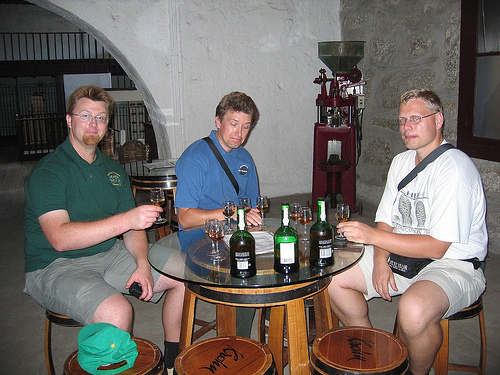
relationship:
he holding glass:
[21, 83, 189, 369] [142, 185, 167, 228]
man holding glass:
[175, 91, 262, 231] [253, 191, 272, 219]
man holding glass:
[321, 89, 489, 375] [335, 203, 349, 231]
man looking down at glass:
[169, 91, 306, 255] [208, 179, 256, 219]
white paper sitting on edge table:
[218, 225, 286, 267] [147, 217, 365, 289]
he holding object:
[21, 83, 189, 369] [124, 274, 152, 301]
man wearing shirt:
[306, 89, 490, 371] [357, 138, 484, 295]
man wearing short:
[306, 89, 490, 371] [344, 231, 484, 316]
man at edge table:
[321, 89, 489, 375] [147, 217, 365, 289]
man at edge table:
[175, 91, 262, 231] [147, 217, 365, 289]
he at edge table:
[21, 83, 189, 369] [147, 217, 365, 289]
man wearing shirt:
[175, 91, 262, 231] [164, 140, 263, 249]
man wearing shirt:
[321, 89, 489, 375] [387, 177, 455, 247]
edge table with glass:
[147, 217, 365, 289] [203, 215, 215, 256]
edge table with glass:
[147, 217, 365, 289] [206, 220, 224, 262]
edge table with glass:
[147, 217, 365, 289] [221, 200, 235, 229]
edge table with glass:
[147, 217, 365, 289] [237, 197, 249, 211]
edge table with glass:
[147, 217, 365, 289] [333, 202, 349, 239]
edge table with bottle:
[147, 217, 365, 289] [228, 200, 259, 279]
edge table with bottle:
[147, 217, 365, 289] [273, 201, 298, 276]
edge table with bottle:
[147, 217, 365, 289] [307, 197, 334, 269]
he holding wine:
[16, 82, 191, 367] [142, 184, 172, 231]